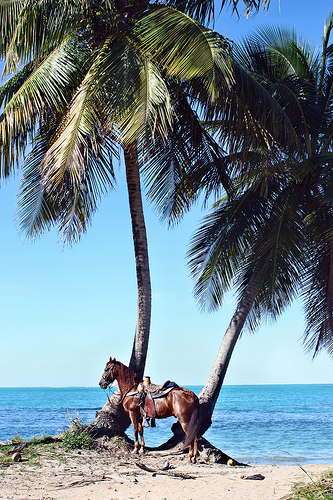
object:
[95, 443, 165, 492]
sand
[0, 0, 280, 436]
tree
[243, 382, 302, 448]
water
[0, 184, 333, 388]
sky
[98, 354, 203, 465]
horse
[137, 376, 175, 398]
saddle